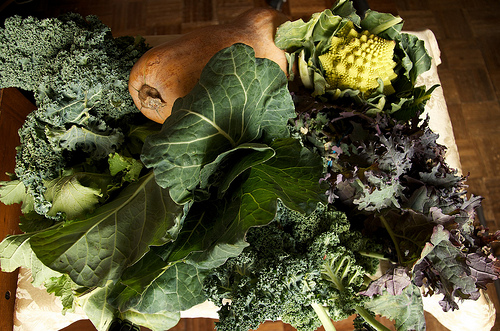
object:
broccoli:
[0, 12, 135, 215]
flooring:
[441, 0, 497, 225]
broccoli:
[205, 206, 368, 330]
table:
[0, 0, 493, 327]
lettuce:
[0, 43, 329, 324]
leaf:
[135, 40, 320, 272]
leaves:
[290, 69, 487, 329]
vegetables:
[3, 10, 496, 325]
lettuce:
[311, 108, 497, 312]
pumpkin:
[127, 2, 304, 127]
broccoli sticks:
[1, 15, 151, 217]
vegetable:
[290, 11, 429, 95]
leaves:
[289, 6, 319, 81]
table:
[444, 56, 496, 156]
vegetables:
[129, 47, 436, 317]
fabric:
[11, 29, 500, 331]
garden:
[0, 10, 490, 330]